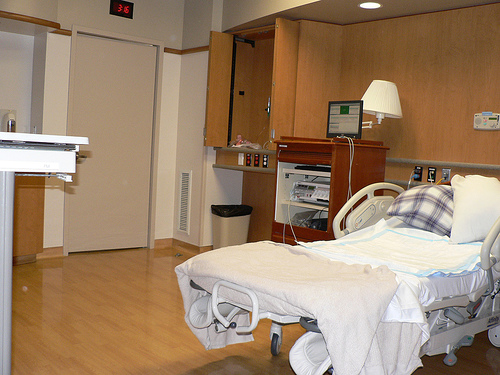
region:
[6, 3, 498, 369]
bed in room in hospital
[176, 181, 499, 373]
adjustable hospital bed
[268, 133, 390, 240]
cabinet with monitors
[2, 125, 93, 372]
adjustable table for hospital bed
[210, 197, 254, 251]
trash can with black liner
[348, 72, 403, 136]
lamp beside bed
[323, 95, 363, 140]
monitor on top of cabinet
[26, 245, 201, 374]
wood floor in hospital room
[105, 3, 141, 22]
digital clock above door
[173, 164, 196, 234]
air vent in wall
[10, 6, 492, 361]
A hospital room.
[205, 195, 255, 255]
A garbage bin with a black garbage bag in it.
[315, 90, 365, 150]
A computer monitor.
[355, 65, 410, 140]
A lamp.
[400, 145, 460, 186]
Three electrical outlets behind the bed.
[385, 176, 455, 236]
A pillow in a plaid pillow case.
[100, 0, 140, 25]
A clock above the door.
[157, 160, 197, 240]
An air conditioning vent.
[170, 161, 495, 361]
A hospital bed.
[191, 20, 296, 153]
A large wooden cabinet.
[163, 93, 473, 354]
A hospital bed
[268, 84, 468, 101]
A lamp on the wall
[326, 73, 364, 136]
A LCD screen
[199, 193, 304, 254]
A trash can in the room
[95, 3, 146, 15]
A clock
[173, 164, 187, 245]
An air vent in the wall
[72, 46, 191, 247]
The door to the room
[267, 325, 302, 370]
Wheels on the bed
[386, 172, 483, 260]
Pillow on the bed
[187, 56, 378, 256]
Storage in the room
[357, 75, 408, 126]
lamp with white shade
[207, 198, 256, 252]
trash can with black bag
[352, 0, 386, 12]
recessed light over bed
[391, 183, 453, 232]
plaid pillowcase on pillow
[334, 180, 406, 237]
rail on hospital bed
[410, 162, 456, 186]
plugs and wires on wall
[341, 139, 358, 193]
wires hanging over table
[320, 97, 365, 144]
computer screen on table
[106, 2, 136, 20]
red digital numbers above door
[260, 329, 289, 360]
black wheel underneath bed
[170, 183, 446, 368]
Hospital bed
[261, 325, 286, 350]
Wheel on the bed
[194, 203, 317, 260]
Trash can in the room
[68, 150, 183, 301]
The door in the room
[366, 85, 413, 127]
A lamp on the wall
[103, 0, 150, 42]
A digital clock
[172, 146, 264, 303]
An air vent on the wall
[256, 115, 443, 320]
A console for electronics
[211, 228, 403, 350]
A blanket